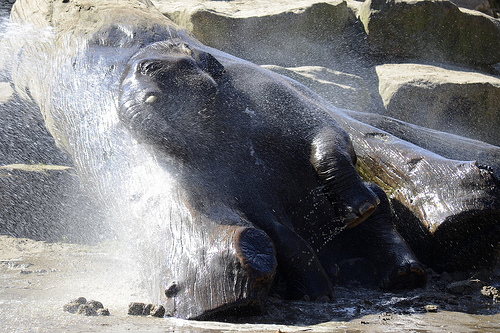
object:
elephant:
[115, 38, 427, 320]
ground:
[0, 229, 497, 333]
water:
[36, 113, 131, 192]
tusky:
[145, 95, 158, 102]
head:
[118, 41, 229, 141]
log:
[0, 0, 498, 333]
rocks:
[365, 63, 499, 144]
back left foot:
[377, 254, 429, 293]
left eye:
[137, 58, 163, 75]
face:
[117, 57, 184, 116]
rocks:
[348, 279, 498, 315]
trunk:
[111, 91, 192, 163]